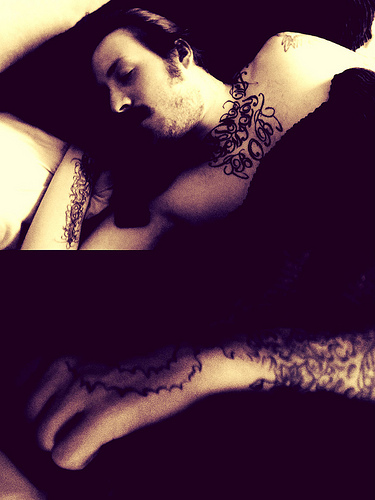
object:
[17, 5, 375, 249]
man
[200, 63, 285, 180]
tattoo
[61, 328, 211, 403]
tattoo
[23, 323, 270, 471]
hand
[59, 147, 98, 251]
tattoo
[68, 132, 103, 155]
wrist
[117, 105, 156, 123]
mustache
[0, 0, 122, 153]
pillow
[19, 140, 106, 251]
arm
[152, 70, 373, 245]
blanket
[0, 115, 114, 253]
pillow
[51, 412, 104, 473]
fingers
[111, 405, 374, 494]
blanket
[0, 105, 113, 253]
sheets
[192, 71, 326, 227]
chest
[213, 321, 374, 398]
tattoo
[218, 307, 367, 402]
forearm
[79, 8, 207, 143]
head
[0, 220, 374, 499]
bedcover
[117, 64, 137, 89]
eyes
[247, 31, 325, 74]
shoulder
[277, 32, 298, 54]
tattoo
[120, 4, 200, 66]
hair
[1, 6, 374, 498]
picture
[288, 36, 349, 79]
sun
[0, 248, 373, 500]
close up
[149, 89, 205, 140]
beard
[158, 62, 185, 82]
side burn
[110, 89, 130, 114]
nose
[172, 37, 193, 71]
ear